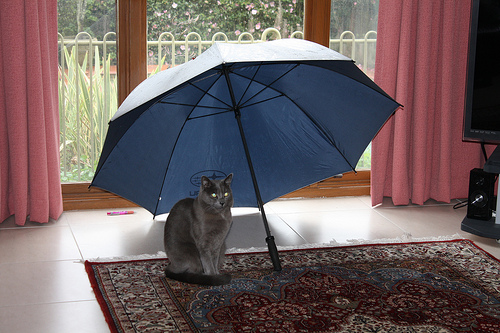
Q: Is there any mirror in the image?
A: No, there are no mirrors.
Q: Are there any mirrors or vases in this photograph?
A: No, there are no mirrors or vases.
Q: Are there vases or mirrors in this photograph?
A: No, there are no mirrors or vases.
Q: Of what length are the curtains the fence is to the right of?
A: The curtains are long.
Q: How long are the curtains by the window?
A: The curtains are long.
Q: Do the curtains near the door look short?
A: No, the curtains are long.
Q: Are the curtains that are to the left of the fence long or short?
A: The curtains are long.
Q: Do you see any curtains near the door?
A: Yes, there are curtains near the door.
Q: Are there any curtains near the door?
A: Yes, there are curtains near the door.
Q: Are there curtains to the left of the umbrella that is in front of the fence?
A: Yes, there are curtains to the left of the umbrella.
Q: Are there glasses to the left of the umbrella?
A: No, there are curtains to the left of the umbrella.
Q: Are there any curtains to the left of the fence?
A: Yes, there are curtains to the left of the fence.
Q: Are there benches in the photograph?
A: No, there are no benches.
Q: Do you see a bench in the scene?
A: No, there are no benches.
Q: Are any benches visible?
A: No, there are no benches.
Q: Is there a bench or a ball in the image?
A: No, there are no benches or balls.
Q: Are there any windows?
A: Yes, there is a window.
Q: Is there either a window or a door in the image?
A: Yes, there is a window.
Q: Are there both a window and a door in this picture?
A: Yes, there are both a window and a door.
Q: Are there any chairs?
A: No, there are no chairs.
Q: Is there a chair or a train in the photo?
A: No, there are no chairs or trains.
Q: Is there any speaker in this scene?
A: Yes, there are speakers.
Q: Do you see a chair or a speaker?
A: Yes, there are speakers.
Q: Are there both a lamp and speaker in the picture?
A: No, there are speakers but no lamps.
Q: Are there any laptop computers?
A: No, there are no laptop computers.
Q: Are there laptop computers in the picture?
A: No, there are no laptop computers.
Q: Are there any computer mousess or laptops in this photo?
A: No, there are no laptops or computer mousess.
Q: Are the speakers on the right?
A: Yes, the speakers are on the right of the image.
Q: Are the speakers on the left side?
A: No, the speakers are on the right of the image.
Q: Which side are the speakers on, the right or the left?
A: The speakers are on the right of the image.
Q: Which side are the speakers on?
A: The speakers are on the right of the image.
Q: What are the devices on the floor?
A: The devices are speakers.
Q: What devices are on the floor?
A: The devices are speakers.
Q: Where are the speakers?
A: The speakers are on the floor.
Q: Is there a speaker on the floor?
A: Yes, there are speakers on the floor.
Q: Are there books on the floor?
A: No, there are speakers on the floor.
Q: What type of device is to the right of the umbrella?
A: The devices are speakers.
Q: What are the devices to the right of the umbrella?
A: The devices are speakers.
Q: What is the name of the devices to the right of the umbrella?
A: The devices are speakers.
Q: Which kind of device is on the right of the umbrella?
A: The devices are speakers.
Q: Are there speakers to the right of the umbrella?
A: Yes, there are speakers to the right of the umbrella.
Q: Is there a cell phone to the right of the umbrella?
A: No, there are speakers to the right of the umbrella.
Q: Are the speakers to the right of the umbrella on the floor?
A: Yes, the speakers are to the right of the umbrella.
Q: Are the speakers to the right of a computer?
A: No, the speakers are to the right of the umbrella.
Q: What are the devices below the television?
A: The devices are speakers.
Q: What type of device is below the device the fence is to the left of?
A: The devices are speakers.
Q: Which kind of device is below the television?
A: The devices are speakers.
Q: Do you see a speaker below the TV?
A: Yes, there are speakers below the TV.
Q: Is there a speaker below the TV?
A: Yes, there are speakers below the TV.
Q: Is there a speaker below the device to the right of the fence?
A: Yes, there are speakers below the TV.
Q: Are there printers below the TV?
A: No, there are speakers below the TV.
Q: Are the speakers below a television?
A: Yes, the speakers are below a television.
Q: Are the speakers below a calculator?
A: No, the speakers are below a television.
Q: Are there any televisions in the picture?
A: Yes, there is a television.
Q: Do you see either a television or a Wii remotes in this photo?
A: Yes, there is a television.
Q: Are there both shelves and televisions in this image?
A: No, there is a television but no shelves.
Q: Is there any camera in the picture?
A: No, there are no cameras.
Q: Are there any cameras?
A: No, there are no cameras.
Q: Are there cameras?
A: No, there are no cameras.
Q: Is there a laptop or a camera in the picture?
A: No, there are no cameras or laptops.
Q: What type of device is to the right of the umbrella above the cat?
A: The device is a television.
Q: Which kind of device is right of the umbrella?
A: The device is a television.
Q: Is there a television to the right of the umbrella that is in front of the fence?
A: Yes, there is a television to the right of the umbrella.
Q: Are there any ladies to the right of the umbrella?
A: No, there is a television to the right of the umbrella.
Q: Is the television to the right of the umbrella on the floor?
A: Yes, the television is to the right of the umbrella.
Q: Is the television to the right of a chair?
A: No, the television is to the right of the umbrella.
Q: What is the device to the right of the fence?
A: The device is a television.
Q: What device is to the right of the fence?
A: The device is a television.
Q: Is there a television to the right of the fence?
A: Yes, there is a television to the right of the fence.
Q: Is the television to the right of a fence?
A: Yes, the television is to the right of a fence.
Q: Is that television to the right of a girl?
A: No, the television is to the right of a fence.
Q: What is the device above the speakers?
A: The device is a television.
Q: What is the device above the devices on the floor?
A: The device is a television.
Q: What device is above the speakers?
A: The device is a television.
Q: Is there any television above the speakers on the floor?
A: Yes, there is a television above the speakers.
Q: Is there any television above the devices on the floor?
A: Yes, there is a television above the speakers.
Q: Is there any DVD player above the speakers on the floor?
A: No, there is a television above the speakers.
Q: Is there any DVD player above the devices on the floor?
A: No, there is a television above the speakers.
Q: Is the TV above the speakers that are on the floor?
A: Yes, the TV is above the speakers.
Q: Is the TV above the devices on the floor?
A: Yes, the TV is above the speakers.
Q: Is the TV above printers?
A: No, the TV is above the speakers.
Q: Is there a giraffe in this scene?
A: No, there are no giraffes.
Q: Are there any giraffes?
A: No, there are no giraffes.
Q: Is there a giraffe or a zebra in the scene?
A: No, there are no giraffes or zebras.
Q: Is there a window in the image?
A: Yes, there is a window.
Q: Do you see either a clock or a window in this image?
A: Yes, there is a window.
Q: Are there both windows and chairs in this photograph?
A: No, there is a window but no chairs.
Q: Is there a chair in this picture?
A: No, there are no chairs.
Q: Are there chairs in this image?
A: No, there are no chairs.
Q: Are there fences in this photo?
A: Yes, there is a fence.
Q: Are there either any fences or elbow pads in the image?
A: Yes, there is a fence.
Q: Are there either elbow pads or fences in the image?
A: Yes, there is a fence.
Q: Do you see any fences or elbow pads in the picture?
A: Yes, there is a fence.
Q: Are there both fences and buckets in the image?
A: No, there is a fence but no buckets.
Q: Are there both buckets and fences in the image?
A: No, there is a fence but no buckets.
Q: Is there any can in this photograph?
A: No, there are no cans.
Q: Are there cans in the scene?
A: No, there are no cans.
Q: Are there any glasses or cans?
A: No, there are no cans or glasses.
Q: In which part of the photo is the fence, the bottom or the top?
A: The fence is in the top of the image.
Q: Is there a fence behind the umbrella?
A: Yes, there is a fence behind the umbrella.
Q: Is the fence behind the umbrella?
A: Yes, the fence is behind the umbrella.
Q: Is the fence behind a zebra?
A: No, the fence is behind the umbrella.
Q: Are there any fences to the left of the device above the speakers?
A: Yes, there is a fence to the left of the TV.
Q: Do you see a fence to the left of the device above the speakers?
A: Yes, there is a fence to the left of the TV.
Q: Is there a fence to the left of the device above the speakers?
A: Yes, there is a fence to the left of the TV.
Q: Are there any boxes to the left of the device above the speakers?
A: No, there is a fence to the left of the television.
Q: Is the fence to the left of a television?
A: Yes, the fence is to the left of a television.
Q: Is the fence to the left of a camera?
A: No, the fence is to the left of a television.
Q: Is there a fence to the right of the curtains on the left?
A: Yes, there is a fence to the right of the curtains.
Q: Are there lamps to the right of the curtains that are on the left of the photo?
A: No, there is a fence to the right of the curtains.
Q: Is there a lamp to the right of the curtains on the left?
A: No, there is a fence to the right of the curtains.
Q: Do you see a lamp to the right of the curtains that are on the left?
A: No, there is a fence to the right of the curtains.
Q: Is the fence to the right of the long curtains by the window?
A: Yes, the fence is to the right of the curtains.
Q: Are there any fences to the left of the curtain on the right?
A: Yes, there is a fence to the left of the curtain.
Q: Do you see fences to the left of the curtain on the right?
A: Yes, there is a fence to the left of the curtain.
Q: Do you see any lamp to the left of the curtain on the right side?
A: No, there is a fence to the left of the curtain.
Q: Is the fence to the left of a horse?
A: No, the fence is to the left of a curtain.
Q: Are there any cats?
A: Yes, there is a cat.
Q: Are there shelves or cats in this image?
A: Yes, there is a cat.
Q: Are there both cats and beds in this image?
A: No, there is a cat but no beds.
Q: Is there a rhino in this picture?
A: No, there are no rhinos.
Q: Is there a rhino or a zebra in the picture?
A: No, there are no rhinos or zebras.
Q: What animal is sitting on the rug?
A: The animal is a cat.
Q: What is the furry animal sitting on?
A: The cat is sitting on the rug.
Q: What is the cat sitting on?
A: The cat is sitting on the rug.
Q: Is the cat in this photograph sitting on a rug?
A: Yes, the cat is sitting on a rug.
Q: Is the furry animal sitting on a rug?
A: Yes, the cat is sitting on a rug.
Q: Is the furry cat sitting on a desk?
A: No, the cat is sitting on a rug.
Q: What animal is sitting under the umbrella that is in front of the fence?
A: The cat is sitting under the umbrella.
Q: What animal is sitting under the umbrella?
A: The animal is a cat.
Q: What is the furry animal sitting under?
A: The cat is sitting under the umbrella.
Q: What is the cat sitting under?
A: The cat is sitting under the umbrella.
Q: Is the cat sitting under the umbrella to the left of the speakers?
A: Yes, the cat is sitting under the umbrella.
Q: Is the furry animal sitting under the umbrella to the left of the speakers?
A: Yes, the cat is sitting under the umbrella.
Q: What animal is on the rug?
A: The cat is on the rug.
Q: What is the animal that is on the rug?
A: The animal is a cat.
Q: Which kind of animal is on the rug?
A: The animal is a cat.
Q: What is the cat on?
A: The cat is on the rug.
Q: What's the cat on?
A: The cat is on the rug.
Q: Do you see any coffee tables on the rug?
A: No, there is a cat on the rug.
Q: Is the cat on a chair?
A: No, the cat is on a rug.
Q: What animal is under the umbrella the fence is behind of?
A: The cat is under the umbrella.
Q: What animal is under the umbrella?
A: The cat is under the umbrella.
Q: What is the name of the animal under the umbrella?
A: The animal is a cat.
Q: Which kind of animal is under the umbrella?
A: The animal is a cat.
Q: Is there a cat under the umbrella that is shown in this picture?
A: Yes, there is a cat under the umbrella.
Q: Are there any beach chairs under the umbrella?
A: No, there is a cat under the umbrella.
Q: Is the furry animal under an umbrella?
A: Yes, the cat is under an umbrella.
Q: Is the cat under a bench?
A: No, the cat is under an umbrella.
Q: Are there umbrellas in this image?
A: Yes, there is an umbrella.